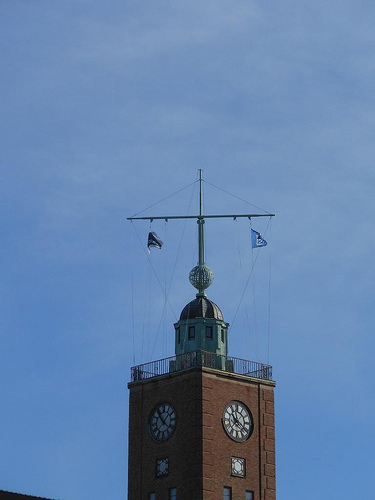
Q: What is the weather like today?
A: It is clear.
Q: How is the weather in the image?
A: It is clear.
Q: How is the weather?
A: It is clear.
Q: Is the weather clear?
A: Yes, it is clear.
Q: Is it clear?
A: Yes, it is clear.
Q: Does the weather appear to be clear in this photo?
A: Yes, it is clear.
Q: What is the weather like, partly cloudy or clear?
A: It is clear.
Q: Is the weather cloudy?
A: No, it is clear.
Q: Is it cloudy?
A: No, it is clear.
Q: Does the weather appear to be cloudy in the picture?
A: No, it is clear.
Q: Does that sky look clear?
A: Yes, the sky is clear.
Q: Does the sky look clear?
A: Yes, the sky is clear.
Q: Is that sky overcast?
A: No, the sky is clear.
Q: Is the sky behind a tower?
A: Yes, the sky is behind a tower.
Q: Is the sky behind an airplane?
A: No, the sky is behind a tower.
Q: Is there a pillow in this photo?
A: No, there are no pillows.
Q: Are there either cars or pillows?
A: No, there are no pillows or cars.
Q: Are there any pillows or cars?
A: No, there are no pillows or cars.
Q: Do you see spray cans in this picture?
A: No, there are no spray cans.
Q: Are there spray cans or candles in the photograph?
A: No, there are no spray cans or candles.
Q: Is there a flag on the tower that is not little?
A: Yes, there are flags on the tower.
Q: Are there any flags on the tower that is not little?
A: Yes, there are flags on the tower.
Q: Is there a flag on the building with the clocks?
A: Yes, there are flags on the tower.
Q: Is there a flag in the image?
A: Yes, there is a flag.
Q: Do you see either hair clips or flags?
A: Yes, there is a flag.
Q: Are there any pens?
A: No, there are no pens.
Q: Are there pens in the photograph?
A: No, there are no pens.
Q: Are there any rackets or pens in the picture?
A: No, there are no pens or rackets.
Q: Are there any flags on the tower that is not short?
A: Yes, there is a flag on the tower.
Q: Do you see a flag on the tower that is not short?
A: Yes, there is a flag on the tower.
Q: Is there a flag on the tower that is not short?
A: Yes, there is a flag on the tower.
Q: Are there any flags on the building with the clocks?
A: Yes, there is a flag on the tower.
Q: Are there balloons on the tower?
A: No, there is a flag on the tower.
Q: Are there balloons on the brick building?
A: No, there is a flag on the tower.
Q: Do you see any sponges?
A: No, there are no sponges.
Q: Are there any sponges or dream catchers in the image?
A: No, there are no sponges or dream catchers.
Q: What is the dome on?
A: The dome is on the tower.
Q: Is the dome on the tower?
A: Yes, the dome is on the tower.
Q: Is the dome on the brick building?
A: Yes, the dome is on the tower.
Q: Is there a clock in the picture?
A: Yes, there is a clock.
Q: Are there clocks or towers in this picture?
A: Yes, there is a clock.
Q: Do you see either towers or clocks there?
A: Yes, there is a clock.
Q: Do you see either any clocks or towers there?
A: Yes, there is a clock.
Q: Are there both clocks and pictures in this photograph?
A: No, there is a clock but no pictures.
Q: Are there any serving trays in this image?
A: No, there are no serving trays.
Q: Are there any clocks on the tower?
A: Yes, there is a clock on the tower.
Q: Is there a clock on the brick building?
A: Yes, there is a clock on the tower.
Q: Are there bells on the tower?
A: No, there is a clock on the tower.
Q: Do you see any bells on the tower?
A: No, there is a clock on the tower.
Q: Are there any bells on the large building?
A: No, there is a clock on the tower.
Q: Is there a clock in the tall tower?
A: Yes, there is a clock in the tower.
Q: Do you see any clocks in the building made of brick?
A: Yes, there is a clock in the tower.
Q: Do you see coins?
A: No, there are no coins.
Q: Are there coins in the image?
A: No, there are no coins.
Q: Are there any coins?
A: No, there are no coins.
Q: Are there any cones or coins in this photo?
A: No, there are no coins or cones.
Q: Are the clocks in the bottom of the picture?
A: Yes, the clocks are in the bottom of the image.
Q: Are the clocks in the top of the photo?
A: No, the clocks are in the bottom of the image.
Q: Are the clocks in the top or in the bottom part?
A: The clocks are in the bottom of the image.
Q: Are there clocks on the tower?
A: Yes, there are clocks on the tower.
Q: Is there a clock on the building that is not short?
A: Yes, there are clocks on the tower.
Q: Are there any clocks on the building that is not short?
A: Yes, there are clocks on the tower.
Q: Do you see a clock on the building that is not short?
A: Yes, there are clocks on the tower.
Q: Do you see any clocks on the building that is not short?
A: Yes, there are clocks on the tower.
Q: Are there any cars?
A: No, there are no cars.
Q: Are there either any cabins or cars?
A: No, there are no cars or cabins.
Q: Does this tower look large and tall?
A: Yes, the tower is large and tall.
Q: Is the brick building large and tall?
A: Yes, the tower is large and tall.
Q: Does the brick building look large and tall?
A: Yes, the tower is large and tall.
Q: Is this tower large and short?
A: No, the tower is large but tall.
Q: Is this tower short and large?
A: No, the tower is large but tall.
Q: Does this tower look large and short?
A: No, the tower is large but tall.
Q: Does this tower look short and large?
A: No, the tower is large but tall.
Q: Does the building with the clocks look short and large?
A: No, the tower is large but tall.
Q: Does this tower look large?
A: Yes, the tower is large.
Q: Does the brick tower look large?
A: Yes, the tower is large.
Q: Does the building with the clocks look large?
A: Yes, the tower is large.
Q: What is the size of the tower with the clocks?
A: The tower is large.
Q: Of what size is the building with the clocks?
A: The tower is large.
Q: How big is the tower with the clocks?
A: The tower is large.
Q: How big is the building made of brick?
A: The tower is large.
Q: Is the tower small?
A: No, the tower is large.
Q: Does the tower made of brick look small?
A: No, the tower is large.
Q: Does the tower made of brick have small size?
A: No, the tower is large.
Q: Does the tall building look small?
A: No, the tower is large.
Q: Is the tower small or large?
A: The tower is large.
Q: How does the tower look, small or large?
A: The tower is large.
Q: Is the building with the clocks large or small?
A: The tower is large.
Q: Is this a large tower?
A: Yes, this is a large tower.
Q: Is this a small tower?
A: No, this is a large tower.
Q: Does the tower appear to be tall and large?
A: Yes, the tower is tall and large.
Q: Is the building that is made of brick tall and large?
A: Yes, the tower is tall and large.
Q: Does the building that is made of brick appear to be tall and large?
A: Yes, the tower is tall and large.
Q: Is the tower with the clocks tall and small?
A: No, the tower is tall but large.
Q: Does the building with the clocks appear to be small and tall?
A: No, the tower is tall but large.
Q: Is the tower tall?
A: Yes, the tower is tall.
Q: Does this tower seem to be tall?
A: Yes, the tower is tall.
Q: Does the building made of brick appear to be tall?
A: Yes, the tower is tall.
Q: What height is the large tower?
A: The tower is tall.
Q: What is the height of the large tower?
A: The tower is tall.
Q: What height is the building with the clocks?
A: The tower is tall.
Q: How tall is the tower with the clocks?
A: The tower is tall.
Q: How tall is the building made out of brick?
A: The tower is tall.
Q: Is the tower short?
A: No, the tower is tall.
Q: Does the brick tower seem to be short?
A: No, the tower is tall.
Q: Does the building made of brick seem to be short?
A: No, the tower is tall.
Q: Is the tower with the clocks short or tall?
A: The tower is tall.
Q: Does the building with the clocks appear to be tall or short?
A: The tower is tall.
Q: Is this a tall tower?
A: Yes, this is a tall tower.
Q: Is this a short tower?
A: No, this is a tall tower.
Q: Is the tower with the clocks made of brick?
A: Yes, the tower is made of brick.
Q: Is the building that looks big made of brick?
A: Yes, the tower is made of brick.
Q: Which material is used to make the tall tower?
A: The tower is made of brick.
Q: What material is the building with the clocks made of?
A: The tower is made of brick.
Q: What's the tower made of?
A: The tower is made of brick.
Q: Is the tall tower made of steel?
A: No, the tower is made of brick.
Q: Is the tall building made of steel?
A: No, the tower is made of brick.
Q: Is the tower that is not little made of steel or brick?
A: The tower is made of brick.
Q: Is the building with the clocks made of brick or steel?
A: The tower is made of brick.